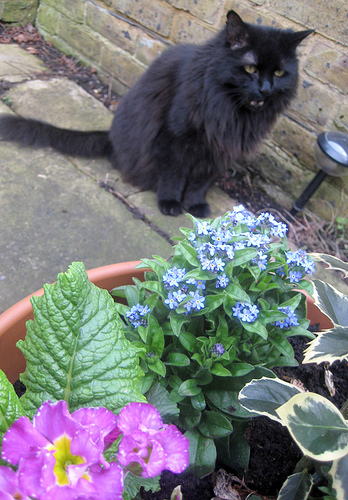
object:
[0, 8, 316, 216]
cat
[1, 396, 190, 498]
flowers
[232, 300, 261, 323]
flowers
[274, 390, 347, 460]
leaf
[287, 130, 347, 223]
light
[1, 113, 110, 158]
tail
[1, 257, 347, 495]
pot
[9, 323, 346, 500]
soil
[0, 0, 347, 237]
wall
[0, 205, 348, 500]
plant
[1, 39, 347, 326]
patio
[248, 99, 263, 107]
bell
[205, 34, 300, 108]
collar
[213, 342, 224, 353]
flower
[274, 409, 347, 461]
edge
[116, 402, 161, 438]
flower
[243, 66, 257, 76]
eye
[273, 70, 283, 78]
eye